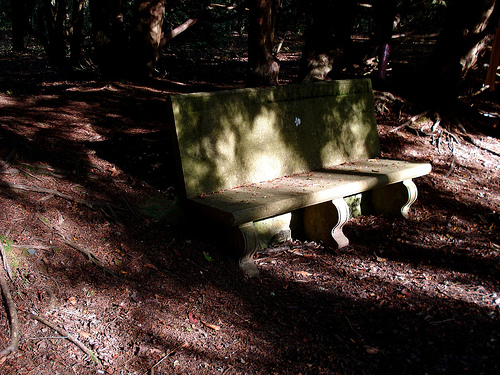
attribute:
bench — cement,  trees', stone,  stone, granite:
[171, 75, 434, 250]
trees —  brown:
[0, 1, 499, 77]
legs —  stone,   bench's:
[306, 197, 352, 253]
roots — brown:
[0, 258, 17, 363]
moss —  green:
[172, 76, 378, 196]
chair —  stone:
[169, 74, 435, 280]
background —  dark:
[4, 0, 93, 78]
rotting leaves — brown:
[1, 81, 176, 372]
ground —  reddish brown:
[3, 227, 259, 371]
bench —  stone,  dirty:
[163, 77, 433, 281]